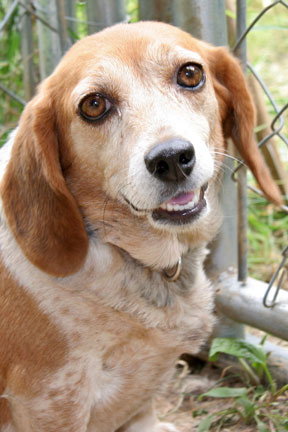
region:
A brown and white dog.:
[0, 19, 283, 431]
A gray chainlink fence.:
[0, 0, 287, 378]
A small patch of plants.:
[159, 336, 286, 431]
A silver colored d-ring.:
[162, 253, 182, 281]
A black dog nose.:
[144, 137, 194, 185]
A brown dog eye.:
[174, 61, 205, 91]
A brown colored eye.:
[77, 90, 114, 122]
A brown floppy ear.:
[0, 97, 90, 278]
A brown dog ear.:
[208, 45, 283, 207]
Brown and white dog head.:
[0, 21, 281, 278]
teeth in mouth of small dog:
[159, 200, 204, 213]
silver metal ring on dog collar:
[155, 250, 188, 285]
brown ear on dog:
[1, 78, 77, 278]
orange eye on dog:
[73, 75, 115, 130]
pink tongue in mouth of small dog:
[168, 186, 196, 206]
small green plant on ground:
[200, 331, 283, 430]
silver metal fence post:
[232, 0, 253, 55]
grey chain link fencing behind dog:
[235, 17, 287, 219]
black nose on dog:
[141, 128, 203, 187]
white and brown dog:
[0, 16, 282, 270]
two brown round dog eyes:
[66, 58, 209, 119]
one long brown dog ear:
[4, 97, 88, 276]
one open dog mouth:
[149, 181, 215, 224]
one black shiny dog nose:
[142, 136, 198, 187]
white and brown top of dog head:
[79, 20, 170, 79]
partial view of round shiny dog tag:
[163, 252, 185, 283]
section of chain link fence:
[237, 11, 287, 305]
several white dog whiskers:
[211, 145, 250, 189]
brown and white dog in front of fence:
[5, 7, 287, 423]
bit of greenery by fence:
[207, 289, 284, 414]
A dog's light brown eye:
[75, 90, 115, 123]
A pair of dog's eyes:
[66, 51, 208, 128]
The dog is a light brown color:
[26, 284, 160, 409]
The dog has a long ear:
[2, 89, 85, 279]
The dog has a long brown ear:
[5, 102, 91, 277]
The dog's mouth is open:
[138, 175, 221, 237]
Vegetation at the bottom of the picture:
[213, 334, 281, 430]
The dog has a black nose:
[142, 136, 202, 186]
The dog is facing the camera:
[21, 26, 286, 232]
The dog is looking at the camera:
[6, 11, 272, 236]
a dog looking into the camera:
[0, 19, 279, 429]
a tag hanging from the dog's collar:
[163, 253, 183, 279]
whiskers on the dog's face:
[98, 153, 146, 238]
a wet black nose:
[142, 137, 195, 179]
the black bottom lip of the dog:
[155, 185, 210, 225]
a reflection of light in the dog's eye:
[184, 63, 195, 76]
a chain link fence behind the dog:
[1, 1, 287, 383]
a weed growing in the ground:
[192, 328, 285, 430]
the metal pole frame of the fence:
[138, 1, 286, 388]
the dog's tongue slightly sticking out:
[169, 188, 195, 205]